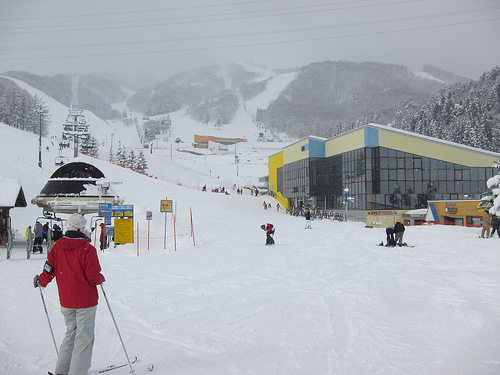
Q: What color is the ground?
A: White.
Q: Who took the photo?
A: A photographer.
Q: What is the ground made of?
A: Snow.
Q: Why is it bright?
A: Sunny.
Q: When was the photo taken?
A: Daytime.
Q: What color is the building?
A: Yellow and blue.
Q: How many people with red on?
A: Two.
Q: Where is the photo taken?
A: At a very snowy ski resort.